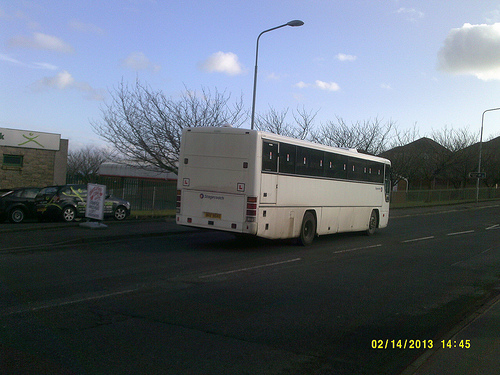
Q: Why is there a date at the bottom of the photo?
A: When the picture was taken.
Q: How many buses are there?
A: 1.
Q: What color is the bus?
A: 1.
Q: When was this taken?
A: Daytime.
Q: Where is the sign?
A: On the left.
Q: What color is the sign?
A: White.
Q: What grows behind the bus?
A: Trees.